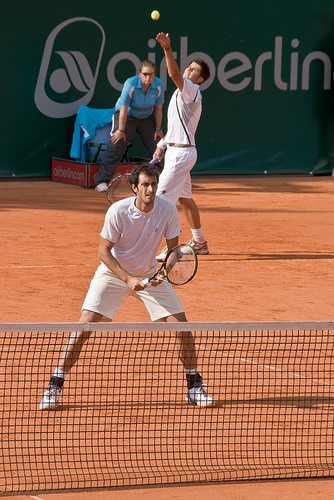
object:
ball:
[151, 10, 160, 21]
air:
[0, 0, 334, 324]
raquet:
[142, 243, 199, 285]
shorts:
[80, 261, 185, 322]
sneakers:
[39, 382, 216, 412]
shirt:
[114, 75, 165, 119]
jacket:
[69, 105, 119, 162]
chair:
[79, 105, 133, 164]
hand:
[127, 275, 147, 291]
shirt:
[165, 77, 202, 146]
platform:
[52, 156, 155, 190]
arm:
[164, 49, 197, 104]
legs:
[56, 267, 197, 376]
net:
[0, 321, 334, 497]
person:
[93, 59, 165, 192]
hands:
[111, 128, 164, 144]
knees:
[109, 135, 163, 152]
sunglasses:
[141, 71, 154, 77]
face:
[139, 66, 155, 84]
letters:
[108, 35, 333, 92]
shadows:
[0, 174, 331, 213]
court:
[0, 173, 331, 499]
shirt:
[100, 196, 181, 276]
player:
[39, 164, 216, 411]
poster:
[0, 1, 334, 177]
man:
[152, 34, 210, 263]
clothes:
[79, 195, 185, 324]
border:
[0, 320, 334, 333]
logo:
[32, 16, 105, 119]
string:
[0, 330, 333, 495]